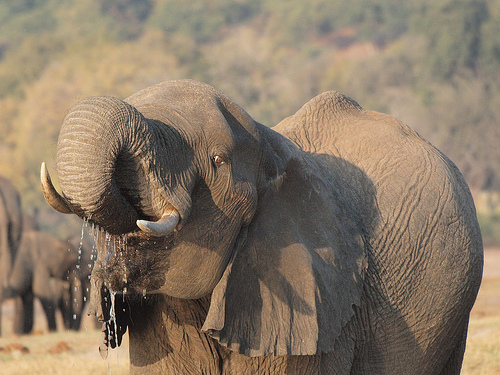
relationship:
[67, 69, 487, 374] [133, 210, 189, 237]
elephant has tusk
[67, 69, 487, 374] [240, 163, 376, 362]
elephant has ear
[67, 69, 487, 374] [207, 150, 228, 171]
elephant has eye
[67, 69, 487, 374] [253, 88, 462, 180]
elephant has back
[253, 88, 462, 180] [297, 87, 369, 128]
back has hump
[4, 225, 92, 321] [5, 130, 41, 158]
elephant in background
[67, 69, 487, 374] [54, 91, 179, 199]
elephant has trunk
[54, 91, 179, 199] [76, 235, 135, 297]
trunk has water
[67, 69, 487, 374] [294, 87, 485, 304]
elephant has skin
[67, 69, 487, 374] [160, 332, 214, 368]
elephant has stomach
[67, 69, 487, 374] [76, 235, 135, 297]
elephant has water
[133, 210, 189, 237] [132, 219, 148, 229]
tusk has tip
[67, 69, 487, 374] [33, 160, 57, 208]
elephant has tusk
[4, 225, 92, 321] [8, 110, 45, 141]
elephants are in distance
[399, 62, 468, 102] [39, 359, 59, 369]
hillside has grass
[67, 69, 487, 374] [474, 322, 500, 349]
elephant in field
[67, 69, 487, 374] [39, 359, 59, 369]
elephant in grass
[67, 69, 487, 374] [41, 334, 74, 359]
elephant has feces